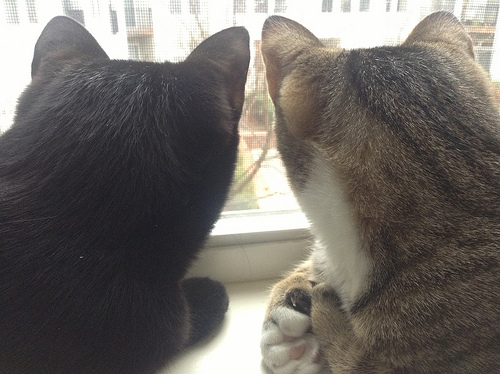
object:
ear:
[257, 10, 324, 100]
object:
[73, 251, 86, 263]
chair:
[263, 8, 477, 208]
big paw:
[261, 284, 329, 372]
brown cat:
[250, 10, 496, 372]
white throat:
[287, 159, 384, 304]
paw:
[183, 277, 226, 342]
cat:
[0, 11, 260, 371]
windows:
[314, 0, 339, 16]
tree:
[171, 3, 288, 213]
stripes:
[335, 40, 498, 226]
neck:
[301, 187, 499, 257]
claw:
[307, 266, 401, 368]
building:
[0, 0, 500, 127]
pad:
[276, 333, 315, 363]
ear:
[402, 11, 475, 55]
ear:
[187, 25, 251, 113]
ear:
[32, 14, 106, 62]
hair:
[263, 15, 293, 44]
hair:
[433, 13, 465, 41]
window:
[1, 0, 497, 241]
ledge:
[204, 211, 317, 280]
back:
[0, 0, 500, 93]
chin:
[279, 171, 349, 241]